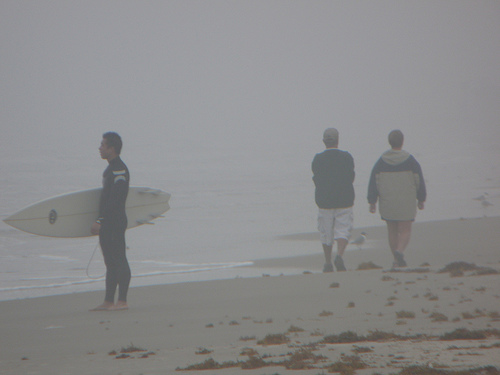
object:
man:
[311, 127, 356, 272]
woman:
[367, 129, 427, 267]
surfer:
[90, 131, 132, 311]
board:
[1, 186, 171, 238]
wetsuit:
[97, 155, 131, 302]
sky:
[0, 0, 500, 155]